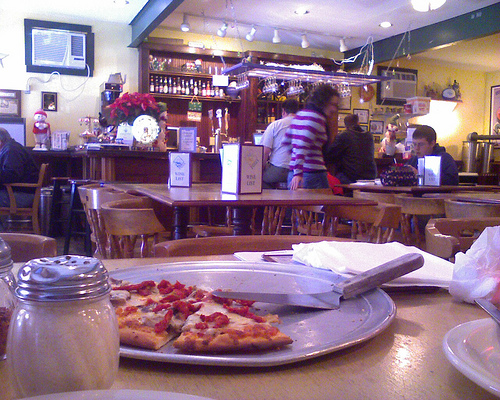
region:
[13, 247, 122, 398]
Container of parmesan cheese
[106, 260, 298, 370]
Slices of pizza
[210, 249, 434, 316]
Metal and wood spatula to serve pizza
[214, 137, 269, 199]
Restaurant menu on a table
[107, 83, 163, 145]
Bouquet of flowers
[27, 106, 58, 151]
Snowman figurine in the background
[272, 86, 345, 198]
Woman in a gray and purple striped shirt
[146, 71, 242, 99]
Shelf of bottles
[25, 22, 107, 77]
White air conditioning unit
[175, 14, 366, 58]
Line of spotlights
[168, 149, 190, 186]
menu on empty table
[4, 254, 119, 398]
parmesan cheese in shaker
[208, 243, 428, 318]
pizza spatula on pizza sheet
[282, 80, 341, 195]
woman with striped shirt and hand on table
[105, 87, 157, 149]
poinsettias on bar counter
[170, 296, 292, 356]
cooked pizza on baking tray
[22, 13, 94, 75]
a/c unit in wall near ceiling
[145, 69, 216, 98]
Liquor for making mixed drinks on shelves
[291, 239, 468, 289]
napkins on table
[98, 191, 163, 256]
wooden round back chair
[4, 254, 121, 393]
Grated cheese in a shaker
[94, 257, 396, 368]
Silver pizza pan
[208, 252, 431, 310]
Spatula for pizza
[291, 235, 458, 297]
White napkins on brown table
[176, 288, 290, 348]
Piece of pizza on a pizza pan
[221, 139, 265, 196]
Menu standing on a table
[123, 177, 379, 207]
Brown table top at a pizza place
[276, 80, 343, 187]
Woman in striped shirt at a pizza place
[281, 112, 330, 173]
Purple striped shirt worn by a woman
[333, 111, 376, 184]
Man in dark coat sitting at a bar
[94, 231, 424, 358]
a silver pizza tray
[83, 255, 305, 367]
pizza on a pizza tray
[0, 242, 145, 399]
parmesan cheese in a glass shaker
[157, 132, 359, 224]
menus on a wood table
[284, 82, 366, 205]
a woman wearing a striped long sleeve shirt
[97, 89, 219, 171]
flowers on top of a bar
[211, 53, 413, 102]
wine glasses hanging from the ceiling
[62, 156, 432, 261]
wooden chairs and tables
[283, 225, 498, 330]
stack of white napkins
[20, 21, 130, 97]
a air conditioner on the wall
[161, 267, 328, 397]
pizza has red pepperonis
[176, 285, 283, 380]
pizza has red pepperonis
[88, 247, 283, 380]
pizza has red pepperonis